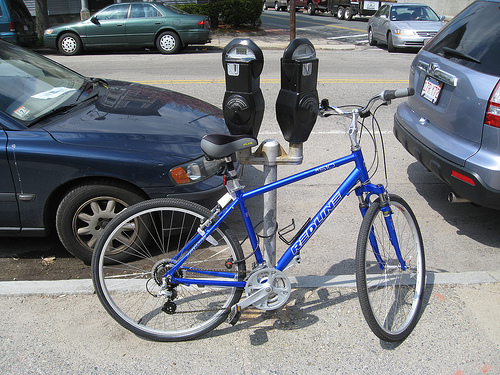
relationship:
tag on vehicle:
[415, 71, 446, 109] [369, 13, 485, 189]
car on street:
[38, 2, 222, 57] [81, 29, 482, 195]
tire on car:
[52, 185, 151, 267] [0, 37, 245, 266]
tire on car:
[57, 32, 82, 56] [43, 2, 214, 57]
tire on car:
[153, 26, 182, 56] [43, 2, 214, 57]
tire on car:
[384, 28, 394, 50] [367, 3, 450, 54]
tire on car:
[365, 26, 375, 47] [367, 3, 450, 54]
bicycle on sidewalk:
[90, 87, 425, 341] [418, 251, 485, 356]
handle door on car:
[105, 22, 128, 33] [49, 4, 218, 65]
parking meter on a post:
[221, 36, 263, 138] [231, 140, 303, 271]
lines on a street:
[127, 79, 412, 84] [20, 40, 494, 370]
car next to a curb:
[0, 37, 247, 261] [18, 252, 310, 344]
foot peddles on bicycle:
[228, 282, 274, 327] [90, 87, 425, 341]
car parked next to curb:
[0, 37, 247, 261] [1, 269, 499, 296]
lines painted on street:
[127, 79, 412, 84] [20, 40, 494, 370]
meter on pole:
[217, 33, 321, 158] [253, 116, 302, 303]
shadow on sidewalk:
[209, 290, 340, 337] [72, 274, 492, 370]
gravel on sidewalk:
[10, 331, 77, 373] [2, 270, 483, 370]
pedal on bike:
[219, 293, 252, 330] [56, 93, 449, 370]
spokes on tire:
[366, 207, 418, 330] [90, 197, 248, 343]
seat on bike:
[198, 132, 258, 158] [85, 85, 430, 349]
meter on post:
[217, 33, 321, 158] [254, 155, 274, 280]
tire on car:
[156, 31, 182, 54] [43, 3, 213, 54]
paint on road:
[162, 70, 416, 97] [7, 52, 498, 374]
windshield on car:
[5, 41, 67, 113] [4, 37, 274, 271]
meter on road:
[274, 37, 319, 156] [0, 0, 499, 375]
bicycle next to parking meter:
[90, 87, 425, 341] [221, 36, 270, 143]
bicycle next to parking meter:
[90, 87, 425, 341] [282, 36, 322, 143]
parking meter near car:
[221, 36, 263, 138] [3, 42, 263, 257]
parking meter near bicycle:
[221, 36, 263, 138] [58, 81, 437, 345]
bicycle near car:
[58, 81, 437, 345] [3, 42, 263, 257]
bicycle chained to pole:
[90, 87, 425, 341] [253, 165, 280, 311]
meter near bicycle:
[269, 34, 321, 158] [90, 87, 425, 341]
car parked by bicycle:
[0, 37, 245, 266] [85, 130, 423, 335]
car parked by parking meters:
[0, 37, 245, 266] [213, 26, 326, 155]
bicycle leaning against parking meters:
[90, 87, 425, 341] [221, 37, 319, 267]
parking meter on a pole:
[91, 25, 437, 367] [255, 135, 288, 275]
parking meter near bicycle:
[91, 25, 437, 367] [90, 87, 425, 341]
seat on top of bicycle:
[200, 133, 259, 159] [58, 81, 437, 345]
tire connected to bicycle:
[71, 173, 252, 357] [90, 87, 425, 341]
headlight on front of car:
[395, 32, 420, 45] [368, 3, 431, 50]